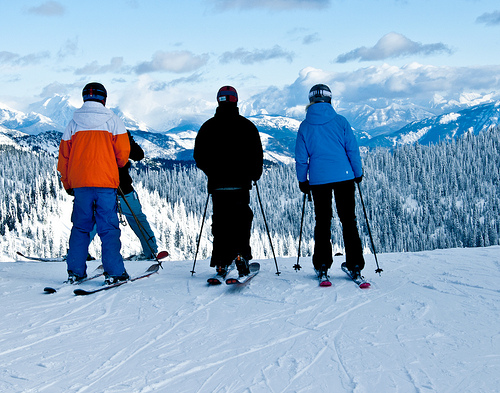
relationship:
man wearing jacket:
[188, 82, 268, 273] [189, 102, 266, 194]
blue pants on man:
[63, 187, 125, 281] [43, 75, 133, 300]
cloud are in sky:
[0, 0, 500, 143] [0, 0, 499, 102]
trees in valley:
[362, 146, 490, 216] [47, 147, 437, 255]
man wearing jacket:
[57, 80, 129, 283] [59, 100, 132, 190]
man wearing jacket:
[192, 84, 264, 271] [193, 104, 263, 191]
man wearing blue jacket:
[294, 83, 363, 274] [293, 82, 366, 278]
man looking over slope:
[294, 83, 363, 274] [3, 257, 498, 387]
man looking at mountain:
[192, 84, 264, 271] [0, 93, 499, 170]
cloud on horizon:
[0, 0, 500, 143] [2, 79, 498, 152]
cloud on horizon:
[203, 3, 333, 11] [2, 79, 498, 152]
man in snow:
[192, 84, 264, 271] [0, 245, 498, 392]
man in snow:
[294, 83, 363, 274] [0, 245, 498, 392]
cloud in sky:
[0, 0, 500, 143] [0, 0, 499, 102]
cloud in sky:
[0, 0, 500, 143] [1, 0, 498, 130]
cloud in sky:
[0, 0, 500, 143] [45, 11, 291, 81]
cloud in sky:
[0, 0, 500, 143] [2, 2, 495, 92]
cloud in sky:
[0, 0, 500, 143] [291, 13, 453, 77]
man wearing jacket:
[40, 71, 150, 296] [61, 100, 128, 183]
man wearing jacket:
[294, 83, 363, 274] [289, 102, 373, 194]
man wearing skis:
[192, 84, 264, 271] [203, 244, 268, 295]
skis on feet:
[41, 258, 168, 294] [57, 264, 128, 286]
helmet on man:
[80, 81, 110, 105] [297, 86, 373, 286]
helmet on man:
[210, 83, 240, 108] [193, 77, 269, 296]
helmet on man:
[302, 80, 337, 107] [61, 77, 141, 302]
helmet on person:
[80, 82, 107, 104] [74, 74, 137, 293]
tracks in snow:
[45, 283, 313, 390] [16, 328, 472, 383]